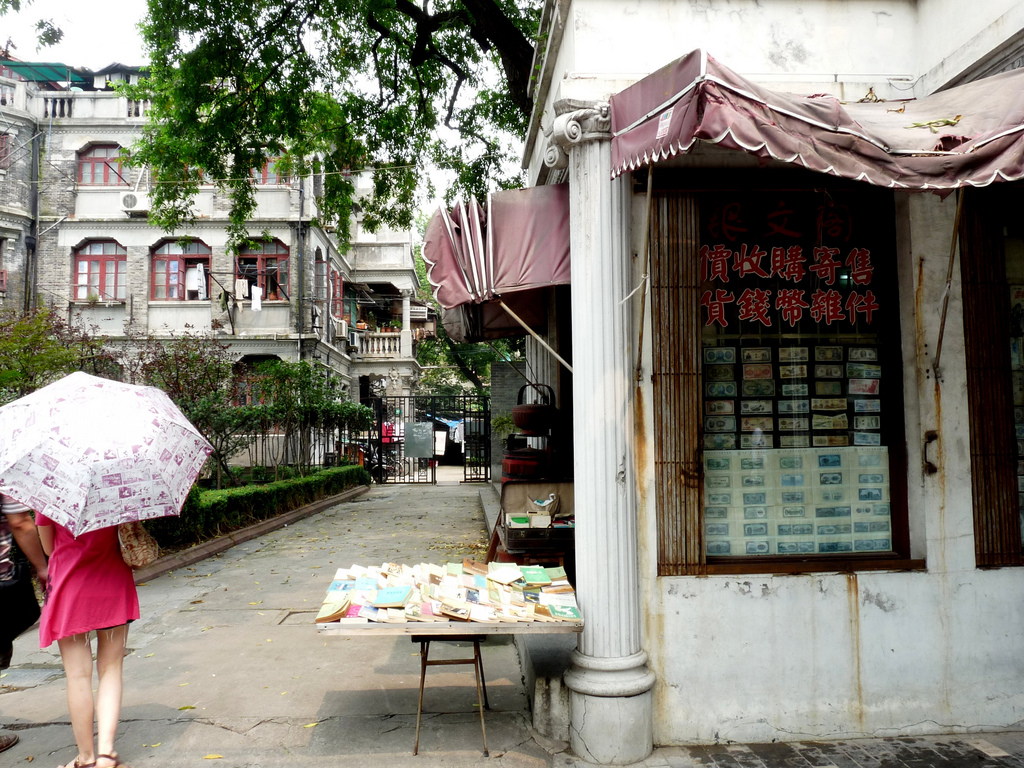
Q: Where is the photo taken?
A: Under an awning.